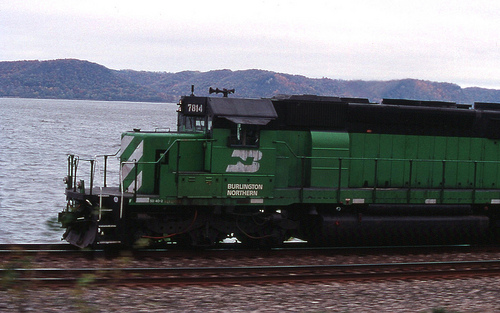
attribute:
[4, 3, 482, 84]
sky — cloudy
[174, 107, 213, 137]
window — framed, small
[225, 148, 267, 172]
sign — white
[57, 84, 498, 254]
train — green, black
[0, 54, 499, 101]
hills — low, brown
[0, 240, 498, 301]
tracks — rail, not being used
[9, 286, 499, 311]
stones — crushed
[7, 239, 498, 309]
tracks — rail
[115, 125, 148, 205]
head — green striped, white striped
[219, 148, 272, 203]
sign — Burlington Northern, painted in white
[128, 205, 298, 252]
wheels — train